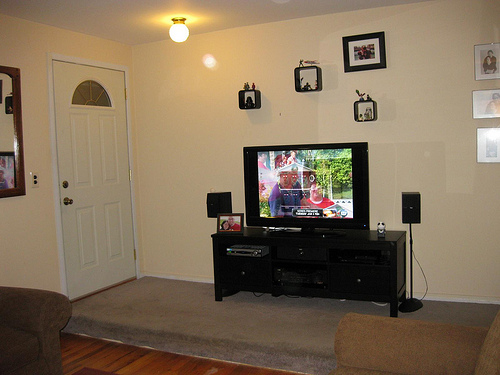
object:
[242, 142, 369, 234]
tv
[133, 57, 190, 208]
wall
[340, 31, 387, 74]
picture frame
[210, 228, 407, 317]
stand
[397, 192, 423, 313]
speaker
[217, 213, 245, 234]
picture frame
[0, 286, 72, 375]
chair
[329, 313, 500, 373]
chair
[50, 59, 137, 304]
door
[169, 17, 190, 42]
light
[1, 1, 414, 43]
ceiling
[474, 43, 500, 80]
picture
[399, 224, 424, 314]
speaker stand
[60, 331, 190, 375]
floor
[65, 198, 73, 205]
handle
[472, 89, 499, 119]
picture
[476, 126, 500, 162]
picture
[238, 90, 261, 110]
shelf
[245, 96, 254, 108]
ornaments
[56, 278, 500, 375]
floor trim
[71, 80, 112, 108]
window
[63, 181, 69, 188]
lock